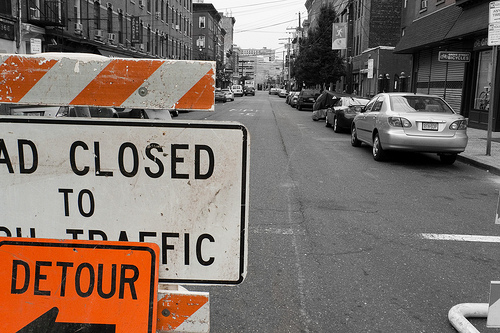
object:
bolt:
[138, 86, 148, 96]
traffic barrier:
[0, 54, 217, 111]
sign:
[0, 115, 251, 287]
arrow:
[11, 306, 116, 332]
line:
[419, 233, 499, 243]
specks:
[3, 56, 20, 101]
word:
[58, 188, 95, 218]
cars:
[324, 96, 371, 133]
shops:
[463, 33, 499, 132]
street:
[173, 92, 499, 332]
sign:
[487, 1, 500, 47]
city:
[0, 0, 498, 331]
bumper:
[381, 143, 469, 154]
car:
[350, 92, 469, 164]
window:
[388, 95, 456, 115]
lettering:
[0, 138, 215, 179]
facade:
[392, 4, 471, 119]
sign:
[0, 235, 160, 332]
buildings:
[191, 2, 227, 89]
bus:
[243, 79, 255, 86]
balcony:
[26, 1, 69, 28]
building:
[0, 0, 193, 60]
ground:
[313, 172, 483, 276]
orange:
[113, 63, 129, 95]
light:
[389, 94, 416, 111]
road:
[173, 90, 500, 331]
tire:
[350, 126, 362, 147]